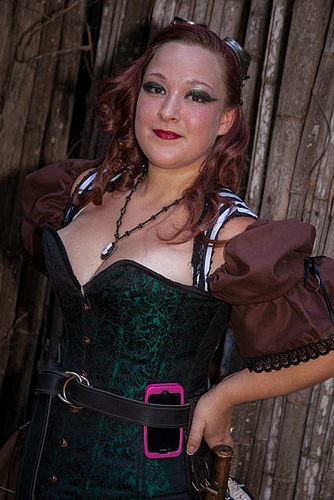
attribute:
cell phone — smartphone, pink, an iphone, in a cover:
[144, 384, 183, 459]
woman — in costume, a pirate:
[6, 23, 332, 500]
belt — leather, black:
[18, 367, 202, 499]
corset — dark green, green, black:
[35, 229, 230, 500]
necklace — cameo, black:
[97, 164, 191, 259]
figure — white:
[103, 242, 117, 256]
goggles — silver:
[170, 14, 254, 74]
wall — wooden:
[6, 2, 333, 388]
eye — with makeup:
[188, 90, 206, 103]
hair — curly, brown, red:
[89, 25, 247, 229]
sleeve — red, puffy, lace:
[208, 221, 333, 375]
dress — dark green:
[14, 158, 333, 500]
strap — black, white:
[190, 185, 252, 292]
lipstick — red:
[155, 129, 180, 142]